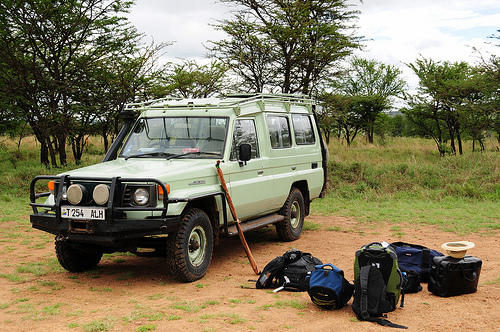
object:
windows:
[266, 115, 317, 150]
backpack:
[350, 262, 408, 329]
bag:
[386, 241, 445, 283]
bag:
[241, 248, 324, 293]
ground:
[0, 130, 499, 330]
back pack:
[304, 263, 356, 311]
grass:
[319, 169, 500, 225]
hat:
[441, 240, 476, 258]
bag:
[428, 254, 482, 298]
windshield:
[120, 117, 228, 159]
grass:
[125, 287, 195, 332]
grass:
[303, 217, 382, 236]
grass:
[389, 221, 410, 238]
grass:
[0, 253, 66, 296]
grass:
[0, 216, 54, 253]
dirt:
[0, 210, 498, 330]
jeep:
[28, 92, 328, 282]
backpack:
[353, 241, 407, 307]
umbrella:
[215, 160, 261, 275]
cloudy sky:
[380, 15, 486, 52]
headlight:
[61, 185, 150, 205]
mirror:
[239, 143, 252, 162]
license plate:
[60, 205, 106, 220]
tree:
[396, 45, 498, 157]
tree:
[311, 42, 409, 147]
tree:
[0, 0, 177, 166]